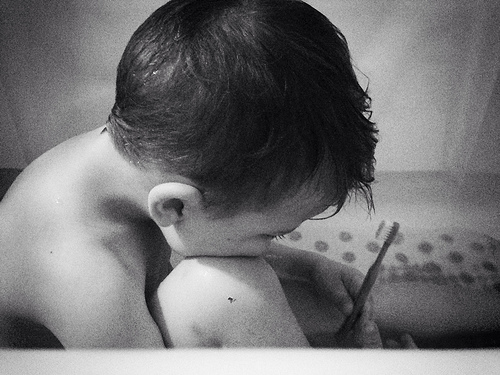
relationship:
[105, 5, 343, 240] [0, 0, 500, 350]
head of boy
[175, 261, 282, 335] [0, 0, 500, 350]
knee of boy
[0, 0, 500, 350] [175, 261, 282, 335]
boy with knee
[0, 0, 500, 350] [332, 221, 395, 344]
boy with toothbrush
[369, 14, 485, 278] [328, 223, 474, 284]
curtain with dots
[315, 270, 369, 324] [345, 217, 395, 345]
hand with toothbrush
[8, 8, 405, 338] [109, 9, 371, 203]
boy with hair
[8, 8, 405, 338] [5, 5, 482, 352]
boy in bathroom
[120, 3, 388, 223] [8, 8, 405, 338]
hair on boy